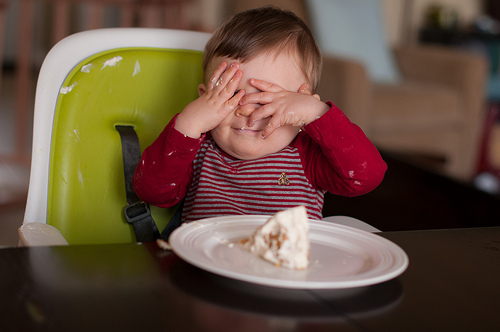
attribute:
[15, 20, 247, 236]
chair — green, white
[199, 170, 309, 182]
stripe — red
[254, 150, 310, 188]
strip — red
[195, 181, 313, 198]
stripe — red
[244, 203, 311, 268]
cake — kept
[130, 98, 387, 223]
shirt — red, striped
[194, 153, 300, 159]
stripe — red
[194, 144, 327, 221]
stripes — red, gray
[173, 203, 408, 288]
plate — white, circular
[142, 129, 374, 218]
shirt — red, striped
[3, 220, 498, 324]
table — black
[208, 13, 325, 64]
hair — brown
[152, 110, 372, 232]
shirt — red, striped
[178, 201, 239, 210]
stripe — red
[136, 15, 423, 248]
kid — little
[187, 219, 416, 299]
plate — white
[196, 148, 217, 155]
stripe — red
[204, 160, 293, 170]
stripe — red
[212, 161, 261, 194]
strip — red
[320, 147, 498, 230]
floor — brown